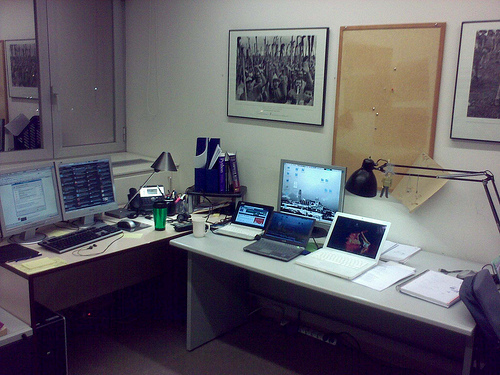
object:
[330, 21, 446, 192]
board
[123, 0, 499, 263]
wall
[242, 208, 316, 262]
laptop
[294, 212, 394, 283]
laptop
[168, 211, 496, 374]
desk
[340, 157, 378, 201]
lamp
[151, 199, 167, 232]
cup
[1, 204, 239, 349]
desk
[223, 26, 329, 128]
art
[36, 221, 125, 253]
keyboard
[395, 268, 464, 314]
notepad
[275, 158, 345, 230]
computer monitor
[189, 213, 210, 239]
mug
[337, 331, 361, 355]
cords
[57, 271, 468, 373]
ground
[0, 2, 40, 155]
mirror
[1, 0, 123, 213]
wall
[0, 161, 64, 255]
computer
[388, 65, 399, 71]
pins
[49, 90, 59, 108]
lever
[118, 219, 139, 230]
mouse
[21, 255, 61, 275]
note papers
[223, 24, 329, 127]
picture frame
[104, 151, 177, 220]
lamp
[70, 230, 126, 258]
ear phones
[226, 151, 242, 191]
book